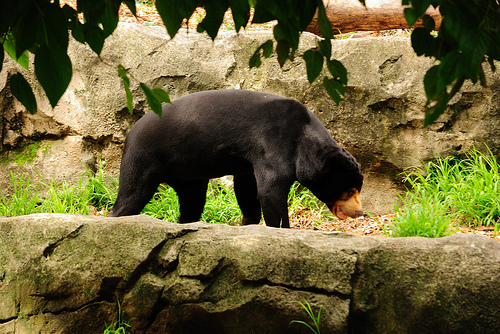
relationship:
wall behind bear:
[0, 25, 500, 217] [110, 89, 367, 229]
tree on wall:
[302, 0, 498, 39] [0, 25, 500, 217]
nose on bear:
[324, 157, 374, 249] [112, 90, 392, 280]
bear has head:
[99, 48, 428, 298] [294, 110, 397, 270]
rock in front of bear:
[51, 147, 405, 306] [128, 84, 408, 278]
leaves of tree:
[397, 166, 437, 226] [375, 82, 465, 251]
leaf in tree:
[309, 65, 362, 110] [289, 2, 463, 160]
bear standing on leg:
[110, 89, 367, 229] [252, 157, 292, 228]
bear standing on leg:
[110, 89, 367, 229] [229, 172, 263, 229]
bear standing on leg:
[110, 89, 367, 229] [108, 113, 175, 214]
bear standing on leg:
[110, 89, 367, 229] [165, 172, 210, 222]